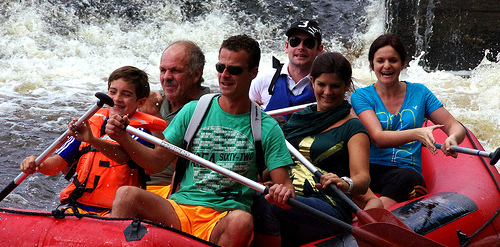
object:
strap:
[170, 93, 219, 198]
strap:
[250, 95, 263, 175]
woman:
[252, 52, 372, 247]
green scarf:
[281, 99, 352, 139]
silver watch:
[341, 176, 354, 194]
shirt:
[278, 100, 371, 220]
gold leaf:
[287, 135, 345, 207]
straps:
[171, 93, 263, 197]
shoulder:
[254, 120, 295, 210]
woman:
[350, 34, 467, 209]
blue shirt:
[350, 81, 446, 176]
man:
[248, 19, 323, 125]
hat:
[285, 19, 322, 49]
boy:
[20, 65, 166, 218]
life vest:
[60, 108, 167, 210]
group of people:
[0, 19, 500, 247]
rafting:
[0, 0, 500, 246]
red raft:
[0, 118, 500, 247]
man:
[104, 35, 293, 247]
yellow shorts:
[161, 198, 253, 247]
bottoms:
[347, 208, 450, 247]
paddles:
[0, 92, 500, 247]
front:
[0, 207, 217, 247]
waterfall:
[7, 4, 496, 39]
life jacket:
[268, 56, 317, 127]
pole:
[115, 114, 360, 234]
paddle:
[109, 117, 449, 247]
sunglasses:
[216, 62, 255, 75]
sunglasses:
[287, 36, 320, 49]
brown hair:
[310, 51, 357, 93]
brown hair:
[368, 33, 408, 74]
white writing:
[391, 150, 412, 164]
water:
[4, 4, 63, 173]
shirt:
[162, 96, 295, 213]